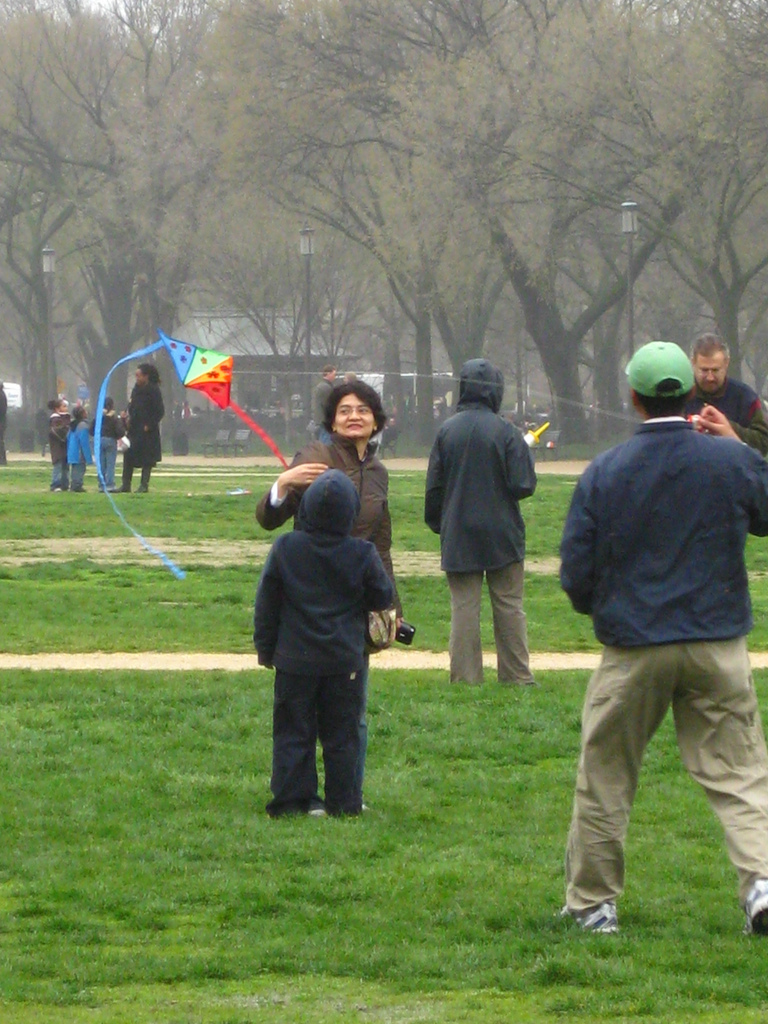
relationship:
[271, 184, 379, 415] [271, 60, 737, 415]
light in park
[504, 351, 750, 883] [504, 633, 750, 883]
man wearing pant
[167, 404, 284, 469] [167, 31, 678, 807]
bench across park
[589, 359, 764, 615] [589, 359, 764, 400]
man wearing hat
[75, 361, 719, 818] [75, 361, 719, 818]
people on grass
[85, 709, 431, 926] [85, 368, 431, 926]
grass under people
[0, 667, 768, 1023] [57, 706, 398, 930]
grass on ground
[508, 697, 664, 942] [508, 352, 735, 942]
leg on person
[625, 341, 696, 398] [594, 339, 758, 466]
green cap on head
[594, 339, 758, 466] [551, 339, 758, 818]
head on person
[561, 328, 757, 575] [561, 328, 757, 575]
jacket on man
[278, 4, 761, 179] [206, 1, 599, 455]
leaves on tree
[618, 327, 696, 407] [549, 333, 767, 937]
green cap on person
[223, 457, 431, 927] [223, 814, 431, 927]
child in grass